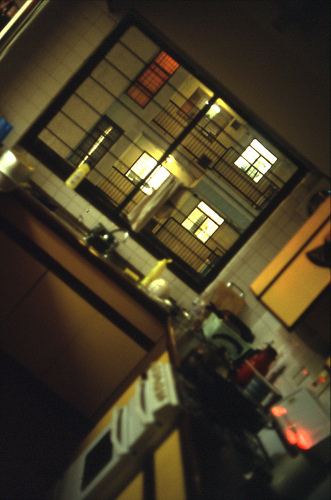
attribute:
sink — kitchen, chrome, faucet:
[40, 195, 125, 260]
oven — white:
[71, 373, 189, 483]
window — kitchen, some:
[29, 48, 313, 246]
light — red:
[100, 53, 188, 116]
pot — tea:
[191, 334, 292, 411]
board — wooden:
[147, 260, 276, 365]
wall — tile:
[204, 43, 291, 123]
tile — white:
[8, 15, 98, 89]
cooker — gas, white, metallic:
[115, 375, 313, 444]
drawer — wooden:
[150, 426, 191, 499]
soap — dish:
[125, 261, 204, 311]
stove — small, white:
[153, 380, 302, 454]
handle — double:
[106, 364, 169, 467]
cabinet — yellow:
[227, 274, 329, 376]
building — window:
[82, 56, 189, 190]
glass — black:
[75, 431, 123, 472]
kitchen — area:
[41, 32, 323, 434]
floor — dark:
[19, 457, 34, 479]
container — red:
[215, 334, 299, 399]